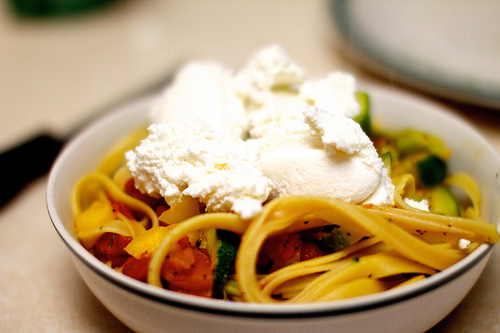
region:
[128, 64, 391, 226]
soft cheese on pasta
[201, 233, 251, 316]
broccoli floret in pasta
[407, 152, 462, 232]
slice of zucchini in pasta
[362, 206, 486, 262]
small flecks on pasta noodles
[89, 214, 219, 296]
hunks of tomato in pasta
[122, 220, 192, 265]
yellow peppers in pasta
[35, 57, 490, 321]
bowl full of pasta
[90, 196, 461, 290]
pasta and vegetable dish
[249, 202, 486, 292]
fettucine noodles in a bowl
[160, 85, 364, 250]
white creamy cheese on pasta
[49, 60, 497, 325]
A bowl of food is shown.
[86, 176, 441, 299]
The food is pasta.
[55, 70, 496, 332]
The bowl is white and blue.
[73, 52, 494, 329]
The bowl of food is in focus.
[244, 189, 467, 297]
The pasta is yellow.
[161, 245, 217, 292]
The red parts are tomato.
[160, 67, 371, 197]
Something white has been added to the top.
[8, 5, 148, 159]
It is blurry in the background.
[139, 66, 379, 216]
The topping looks like ice cream.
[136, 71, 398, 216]
The topping is white.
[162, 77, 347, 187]
ricotta cheese on top of pasta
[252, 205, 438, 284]
linguine noodles in a bowl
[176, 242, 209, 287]
a piece of chopped cooked tomato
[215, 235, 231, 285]
the head of a piece of green broccoli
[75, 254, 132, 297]
a blue rim on a white bowl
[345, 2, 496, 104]
a blurred white plate with a blue rim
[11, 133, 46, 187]
the blurred black handle of a knife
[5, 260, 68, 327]
a beige counter top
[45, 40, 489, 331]
a bowl of vegetable pasta topped with cheese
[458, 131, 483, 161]
a spot of yellow sauce on the side of a bowl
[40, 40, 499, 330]
a bowl of food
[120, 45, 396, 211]
some cheese in the plate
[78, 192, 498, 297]
some pasta in the plate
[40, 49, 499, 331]
the bowl is white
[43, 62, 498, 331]
the bowl has a black stripe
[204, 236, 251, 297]
green vegetable in the plate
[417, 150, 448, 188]
green vegetable in the plate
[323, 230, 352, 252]
green vegetable in the plate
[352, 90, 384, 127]
green vegetable in the plate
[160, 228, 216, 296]
red vegetable in the plate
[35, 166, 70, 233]
edge of a bowl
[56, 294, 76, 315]
part of a table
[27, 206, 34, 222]
edge of a table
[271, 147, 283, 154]
white lamp of food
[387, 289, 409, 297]
black stripe on plate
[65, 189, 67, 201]
inner wall of a bowl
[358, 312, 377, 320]
side of a bowl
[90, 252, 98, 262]
edge of a dish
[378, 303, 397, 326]
a white plate with food